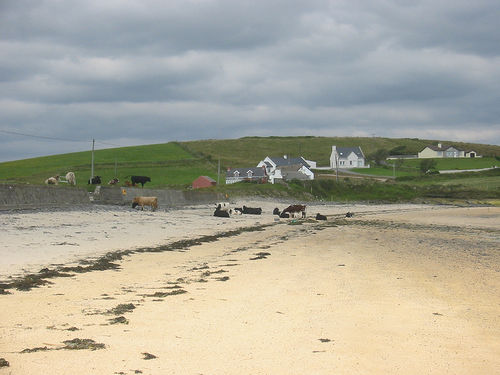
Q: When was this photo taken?
A: During the day.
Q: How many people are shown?
A: None.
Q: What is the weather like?
A: Cloudy.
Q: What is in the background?
A: Houses.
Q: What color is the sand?
A: Brown.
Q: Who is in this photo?
A: No one.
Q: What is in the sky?
A: Clouds.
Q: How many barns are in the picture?
A: One.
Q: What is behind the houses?
A: A hill.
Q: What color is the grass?
A: Green.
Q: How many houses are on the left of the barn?
A: Zero.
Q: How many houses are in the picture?
A: Four.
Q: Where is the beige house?
A: On the far right.